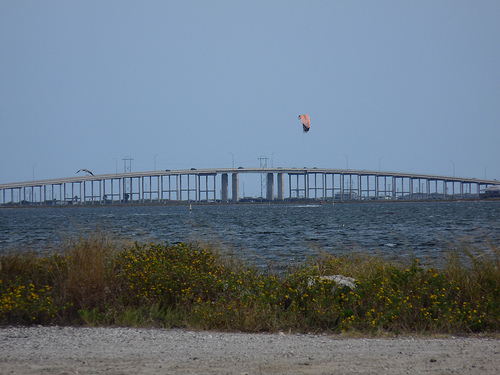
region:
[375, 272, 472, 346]
yellow flowers in plant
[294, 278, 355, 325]
yellow flowers in plant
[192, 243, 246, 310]
yellow flowers in plant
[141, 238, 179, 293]
yellow flowers in plant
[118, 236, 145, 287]
yellow flowers in plant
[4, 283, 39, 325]
yellow flowers in plant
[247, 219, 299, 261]
ripples in ocean water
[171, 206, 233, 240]
ripples in ocean water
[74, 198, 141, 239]
ripples in ocean water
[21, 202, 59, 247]
ripples in ocean water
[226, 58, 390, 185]
a parasail in the sky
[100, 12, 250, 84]
a sky that is blue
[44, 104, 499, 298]
a bridge above the water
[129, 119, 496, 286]
a large bridge above the water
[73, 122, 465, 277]
a long bridge above the water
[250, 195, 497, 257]
a body of water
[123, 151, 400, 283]
a body of water with bridge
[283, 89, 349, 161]
a parasail in the sky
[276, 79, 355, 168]
a parasailing in the wind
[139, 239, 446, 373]
a bushy area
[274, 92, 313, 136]
KITE IN THE SKY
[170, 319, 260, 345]
stones on the sand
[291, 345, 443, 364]
sand on the ground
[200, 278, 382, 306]
weeds on the gruond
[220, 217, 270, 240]
the water is calm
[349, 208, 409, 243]
the body of water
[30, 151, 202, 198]
bridge over the water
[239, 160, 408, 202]
the bridge is long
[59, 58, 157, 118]
he sky is clear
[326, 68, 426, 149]
the weather is sunny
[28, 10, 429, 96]
The sky is the color blue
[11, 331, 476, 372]
The dirt on the ground is brown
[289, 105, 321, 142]
The kite is in the air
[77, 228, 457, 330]
The grass is tall and green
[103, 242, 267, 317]
The flowers are the color green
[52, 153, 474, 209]
The bridge over the water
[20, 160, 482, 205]
The bridge has a small curve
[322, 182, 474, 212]
The buildings on the other side of the bridge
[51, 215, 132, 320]
The grass is dead and the color brown